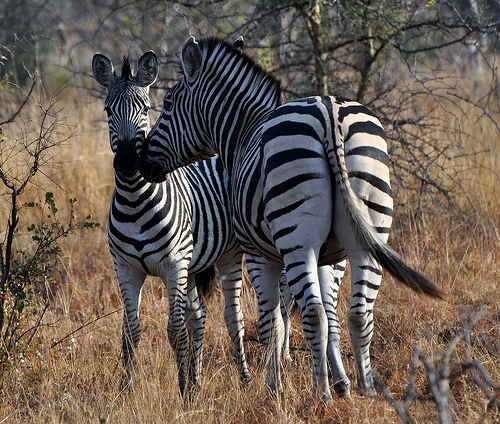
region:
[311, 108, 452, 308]
the tail of a zebra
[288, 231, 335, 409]
the leg of a zebra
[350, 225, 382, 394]
the leg of a zebra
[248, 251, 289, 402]
the leg of a zebra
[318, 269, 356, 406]
the leg of a zebra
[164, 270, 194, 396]
the leg of a zebra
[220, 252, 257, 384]
the leg of a zebra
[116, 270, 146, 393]
the leg of a zebra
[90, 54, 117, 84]
the zebra's ear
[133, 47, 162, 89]
the zebra's ear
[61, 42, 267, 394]
Zebra facing the camera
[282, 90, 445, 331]
Zebra's tail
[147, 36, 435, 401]
Zebra with it's head turned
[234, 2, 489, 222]
Two trees behind the zebras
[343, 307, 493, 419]
Twigs in front of zebras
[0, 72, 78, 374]
Bush to the side of zebras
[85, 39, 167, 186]
Zebra's head who is looking straight forward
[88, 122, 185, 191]
The two zebras' noses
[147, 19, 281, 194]
The head of the zebra with it's head turned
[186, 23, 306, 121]
Mane of the closest zebra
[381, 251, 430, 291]
tail of a zebra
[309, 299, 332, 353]
part of the rear leg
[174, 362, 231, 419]
part of some dry grass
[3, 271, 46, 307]
part of some plant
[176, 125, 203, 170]
jaw of a zebra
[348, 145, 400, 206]
hip of a zebra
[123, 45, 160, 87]
left ear of a zebra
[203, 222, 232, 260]
stomach of a zebra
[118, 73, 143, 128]
head of a zebra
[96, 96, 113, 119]
eye of a zebra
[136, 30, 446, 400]
The zebra facing away from the camera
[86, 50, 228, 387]
The zebra facing the camera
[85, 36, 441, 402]
The zebras the photo is of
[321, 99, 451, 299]
The tail of the zebra facing away from the camera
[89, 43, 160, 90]
Ears of the zebra facing the camera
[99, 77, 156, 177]
Face of the zebra facing the camera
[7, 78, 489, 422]
The grass the zebras are standing on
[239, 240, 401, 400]
The legs of the zebra nearest the camera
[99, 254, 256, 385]
The legs of the zebra furthest from the camera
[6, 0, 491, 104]
The trees in the background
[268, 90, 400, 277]
big zebra, butt end.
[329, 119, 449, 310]
big zebra swishy tail with some flyaway ends at the end.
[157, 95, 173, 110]
big zebra, sad dark eye.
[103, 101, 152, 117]
smaller zebra looks forward.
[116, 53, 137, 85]
smaller zebra's mohican [mohawk] mane from the front.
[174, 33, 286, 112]
big zebra's mane is also black+white striped.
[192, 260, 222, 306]
the end of little zebra's tail is fluffy.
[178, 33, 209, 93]
big zebra's ear turned backwards.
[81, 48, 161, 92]
little zebra's ears face forward.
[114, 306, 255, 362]
little zebra's knees are knobby.